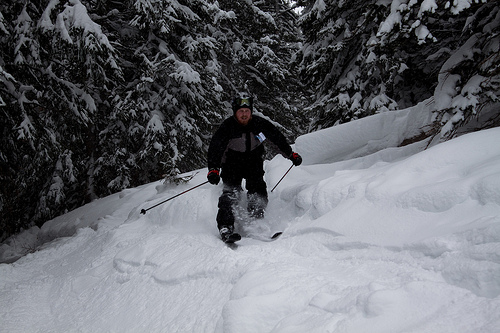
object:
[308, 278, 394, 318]
tracks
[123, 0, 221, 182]
trees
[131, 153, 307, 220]
pole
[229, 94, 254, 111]
hat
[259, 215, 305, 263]
snow ski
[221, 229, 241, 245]
snow ski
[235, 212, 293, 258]
shadows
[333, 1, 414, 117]
trees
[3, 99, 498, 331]
snow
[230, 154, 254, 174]
black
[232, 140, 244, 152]
gray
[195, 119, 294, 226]
snowsuit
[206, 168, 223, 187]
gloves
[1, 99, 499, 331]
area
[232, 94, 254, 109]
hood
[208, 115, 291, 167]
jacket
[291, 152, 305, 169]
glove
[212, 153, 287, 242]
pants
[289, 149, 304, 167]
hand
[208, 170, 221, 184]
hand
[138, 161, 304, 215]
ski pole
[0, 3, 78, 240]
trees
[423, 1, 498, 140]
trees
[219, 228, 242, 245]
ski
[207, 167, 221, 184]
glove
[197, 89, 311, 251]
man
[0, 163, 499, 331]
ground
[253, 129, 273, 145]
ticket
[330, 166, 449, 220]
snow drift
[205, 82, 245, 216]
snow bank